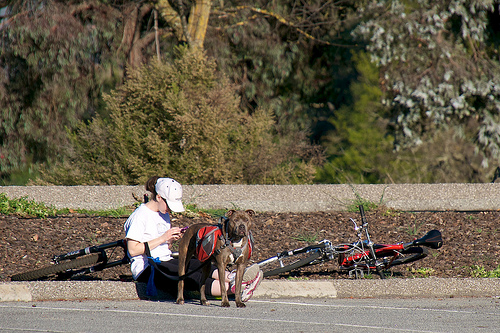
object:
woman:
[126, 174, 187, 298]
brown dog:
[177, 204, 255, 306]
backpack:
[194, 224, 215, 260]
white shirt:
[125, 207, 164, 272]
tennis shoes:
[236, 264, 266, 303]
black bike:
[11, 224, 132, 282]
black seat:
[422, 229, 443, 249]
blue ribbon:
[144, 254, 162, 303]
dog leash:
[141, 232, 238, 288]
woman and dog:
[113, 161, 282, 309]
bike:
[260, 204, 444, 276]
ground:
[281, 189, 334, 218]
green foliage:
[311, 128, 377, 179]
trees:
[184, 84, 240, 168]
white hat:
[147, 175, 189, 215]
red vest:
[194, 232, 222, 248]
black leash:
[138, 242, 236, 279]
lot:
[128, 309, 329, 333]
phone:
[168, 217, 182, 235]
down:
[281, 232, 454, 261]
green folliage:
[347, 72, 398, 91]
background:
[20, 8, 497, 181]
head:
[230, 206, 259, 239]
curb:
[65, 258, 398, 307]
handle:
[345, 199, 373, 226]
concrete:
[349, 302, 441, 328]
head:
[140, 174, 187, 219]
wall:
[422, 187, 471, 207]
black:
[255, 241, 323, 276]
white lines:
[314, 303, 497, 318]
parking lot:
[10, 283, 472, 333]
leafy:
[303, 156, 357, 179]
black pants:
[134, 256, 213, 302]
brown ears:
[245, 209, 259, 219]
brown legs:
[215, 262, 230, 308]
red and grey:
[181, 219, 219, 263]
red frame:
[338, 238, 406, 266]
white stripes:
[140, 304, 370, 327]